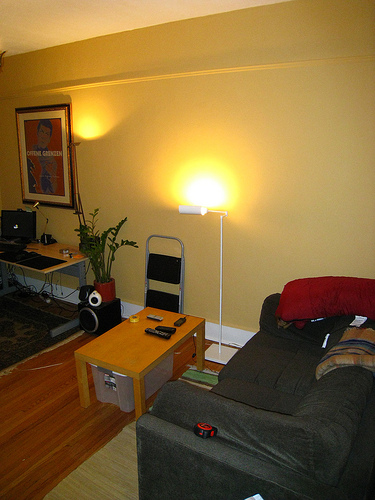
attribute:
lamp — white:
[181, 203, 227, 369]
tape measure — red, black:
[193, 418, 220, 441]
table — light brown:
[62, 291, 218, 421]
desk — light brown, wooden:
[0, 239, 84, 339]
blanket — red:
[274, 275, 373, 324]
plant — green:
[72, 208, 138, 285]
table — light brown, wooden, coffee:
[72, 300, 207, 375]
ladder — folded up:
[143, 233, 184, 312]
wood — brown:
[74, 302, 198, 408]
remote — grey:
[146, 311, 167, 320]